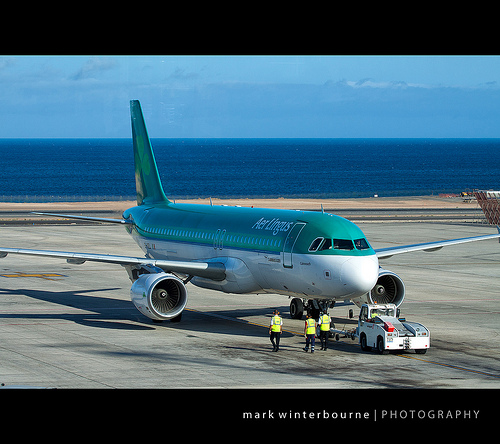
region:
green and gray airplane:
[17, 76, 450, 301]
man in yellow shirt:
[270, 308, 283, 350]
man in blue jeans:
[302, 315, 315, 353]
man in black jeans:
[321, 310, 331, 348]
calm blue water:
[203, 127, 453, 190]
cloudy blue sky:
[166, 67, 439, 117]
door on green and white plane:
[280, 214, 303, 271]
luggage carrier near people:
[350, 302, 432, 353]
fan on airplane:
[142, 274, 188, 319]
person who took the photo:
[239, 403, 499, 416]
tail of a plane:
[127, 99, 168, 202]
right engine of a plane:
[128, 269, 188, 319]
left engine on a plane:
[365, 271, 405, 309]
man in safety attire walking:
[267, 307, 286, 352]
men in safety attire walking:
[302, 311, 331, 351]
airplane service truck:
[334, 301, 431, 351]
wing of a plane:
[0, 243, 221, 279]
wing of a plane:
[375, 233, 498, 260]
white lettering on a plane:
[250, 216, 292, 233]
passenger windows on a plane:
[141, 224, 278, 251]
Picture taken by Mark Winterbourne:
[225, 393, 496, 425]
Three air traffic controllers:
[252, 299, 349, 356]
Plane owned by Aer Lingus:
[236, 206, 303, 246]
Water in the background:
[177, 145, 473, 186]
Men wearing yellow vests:
[256, 295, 346, 353]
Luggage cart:
[335, 288, 455, 356]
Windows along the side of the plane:
[127, 206, 300, 256]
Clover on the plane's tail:
[117, 127, 169, 190]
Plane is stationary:
[55, 135, 390, 315]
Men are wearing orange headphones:
[263, 299, 337, 326]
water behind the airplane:
[0, 137, 499, 199]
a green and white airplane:
[3, 101, 498, 319]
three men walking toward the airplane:
[269, 308, 330, 353]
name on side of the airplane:
[249, 214, 293, 236]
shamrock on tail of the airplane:
[134, 133, 151, 179]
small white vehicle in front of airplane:
[356, 302, 431, 355]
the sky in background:
[3, 56, 498, 136]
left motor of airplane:
[129, 271, 189, 321]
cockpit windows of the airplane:
[309, 235, 369, 250]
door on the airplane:
[281, 221, 307, 269]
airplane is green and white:
[208, 158, 362, 300]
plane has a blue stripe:
[135, 222, 303, 279]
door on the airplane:
[277, 219, 307, 308]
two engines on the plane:
[118, 255, 429, 316]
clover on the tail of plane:
[122, 124, 180, 198]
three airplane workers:
[271, 313, 353, 366]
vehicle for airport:
[354, 301, 453, 393]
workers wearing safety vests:
[256, 304, 365, 350]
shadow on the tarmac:
[31, 284, 167, 382]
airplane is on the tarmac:
[143, 232, 403, 367]